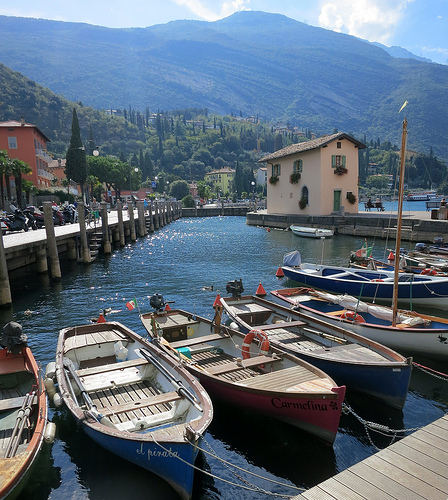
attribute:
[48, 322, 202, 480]
boat — blue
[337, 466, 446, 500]
dock — wood, wooden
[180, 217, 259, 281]
water — blue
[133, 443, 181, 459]
writing — white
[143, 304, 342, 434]
boat — pink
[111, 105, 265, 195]
trees — distant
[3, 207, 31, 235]
motorcycle — parked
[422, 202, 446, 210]
bench — wooden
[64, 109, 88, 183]
tree — growing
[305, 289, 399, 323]
sail — tied down